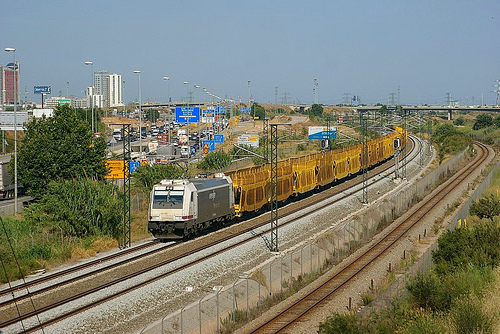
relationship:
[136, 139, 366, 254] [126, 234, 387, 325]
train on tracks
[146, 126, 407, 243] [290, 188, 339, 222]
train on tracks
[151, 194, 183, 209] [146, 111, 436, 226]
window on train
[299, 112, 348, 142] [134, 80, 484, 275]
billboard near tracks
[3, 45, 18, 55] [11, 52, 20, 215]
street light on pole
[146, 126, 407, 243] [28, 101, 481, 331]
train on tracks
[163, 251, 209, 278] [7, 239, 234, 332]
rocks in between track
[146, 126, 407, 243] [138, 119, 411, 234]
train being towed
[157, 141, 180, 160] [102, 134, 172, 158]
truck driving road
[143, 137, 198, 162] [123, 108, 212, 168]
traffic driving road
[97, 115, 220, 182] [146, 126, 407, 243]
road running train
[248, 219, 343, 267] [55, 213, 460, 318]
gravel surrounding tracks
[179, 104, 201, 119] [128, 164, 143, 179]
sign with lettering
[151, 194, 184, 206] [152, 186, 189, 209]
window of train